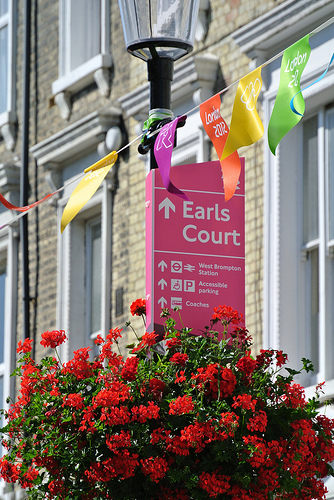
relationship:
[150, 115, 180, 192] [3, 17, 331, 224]
banner on line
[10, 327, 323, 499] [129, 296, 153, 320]
bush with flower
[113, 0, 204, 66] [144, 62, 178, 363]
lamp on pole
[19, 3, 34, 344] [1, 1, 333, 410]
downspout on building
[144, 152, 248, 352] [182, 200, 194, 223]
sign with letter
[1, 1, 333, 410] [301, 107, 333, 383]
building with window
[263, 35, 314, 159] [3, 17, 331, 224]
pennant on line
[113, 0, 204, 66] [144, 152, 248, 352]
lamp above sign